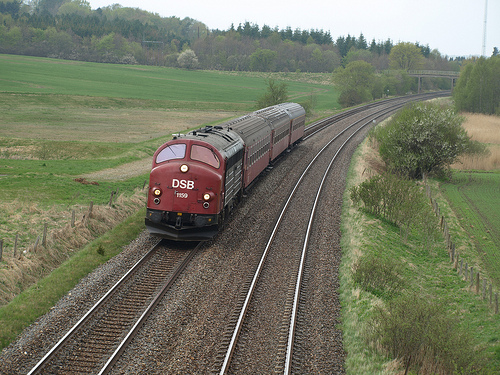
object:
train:
[145, 102, 306, 241]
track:
[31, 240, 164, 375]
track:
[215, 95, 432, 375]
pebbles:
[186, 279, 221, 317]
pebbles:
[312, 270, 338, 364]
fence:
[0, 180, 147, 262]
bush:
[352, 254, 401, 294]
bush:
[353, 178, 422, 224]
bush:
[379, 307, 454, 373]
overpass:
[418, 70, 454, 94]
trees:
[456, 55, 498, 114]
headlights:
[154, 190, 160, 194]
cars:
[222, 102, 305, 189]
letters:
[172, 178, 180, 187]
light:
[203, 194, 209, 200]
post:
[71, 210, 75, 226]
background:
[0, 0, 498, 375]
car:
[282, 102, 305, 145]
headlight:
[180, 164, 189, 172]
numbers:
[181, 193, 185, 198]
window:
[156, 143, 187, 164]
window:
[190, 144, 220, 168]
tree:
[380, 101, 468, 176]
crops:
[448, 175, 500, 282]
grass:
[0, 208, 145, 348]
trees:
[251, 50, 278, 73]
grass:
[21, 167, 93, 203]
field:
[0, 53, 335, 346]